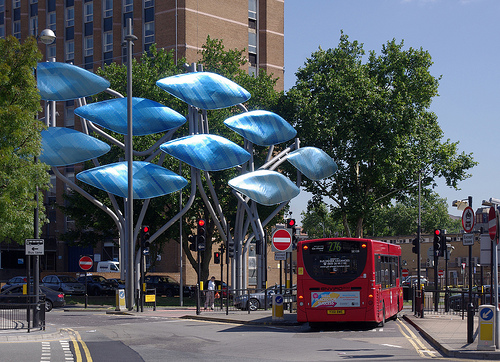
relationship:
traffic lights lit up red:
[134, 216, 454, 261] [430, 227, 445, 239]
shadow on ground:
[178, 307, 345, 333] [3, 278, 473, 359]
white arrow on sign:
[474, 303, 498, 350] [435, 278, 497, 323]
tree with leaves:
[273, 23, 478, 237] [327, 61, 395, 126]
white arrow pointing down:
[474, 303, 498, 350] [466, 292, 498, 335]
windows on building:
[65, 17, 222, 74] [105, 7, 360, 77]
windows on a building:
[65, 17, 222, 74] [0, 3, 286, 98]